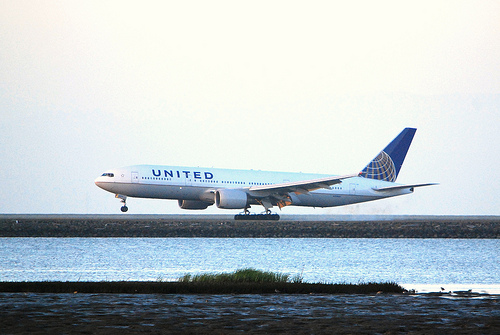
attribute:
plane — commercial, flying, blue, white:
[87, 120, 442, 216]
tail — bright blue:
[355, 124, 436, 180]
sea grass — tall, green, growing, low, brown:
[158, 263, 311, 287]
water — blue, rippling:
[1, 232, 498, 278]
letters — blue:
[150, 163, 217, 184]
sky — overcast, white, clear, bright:
[0, 1, 498, 210]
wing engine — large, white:
[208, 188, 251, 209]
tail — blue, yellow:
[358, 124, 418, 183]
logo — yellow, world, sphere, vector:
[360, 145, 398, 184]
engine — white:
[177, 194, 208, 213]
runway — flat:
[2, 202, 499, 223]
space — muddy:
[3, 292, 499, 330]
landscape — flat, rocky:
[2, 210, 499, 248]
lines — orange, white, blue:
[360, 146, 395, 186]